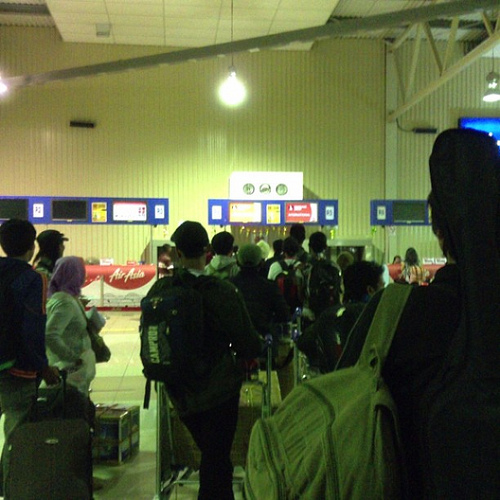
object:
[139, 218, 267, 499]
man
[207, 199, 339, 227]
panels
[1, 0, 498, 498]
airport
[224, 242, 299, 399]
person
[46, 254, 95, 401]
person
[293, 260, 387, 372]
person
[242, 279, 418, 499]
backpack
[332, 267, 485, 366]
shoulder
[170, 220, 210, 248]
black cap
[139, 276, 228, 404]
backpack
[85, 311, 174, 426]
floor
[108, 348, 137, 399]
tiles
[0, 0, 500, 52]
ceiling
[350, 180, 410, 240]
ground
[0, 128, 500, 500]
people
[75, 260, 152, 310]
counter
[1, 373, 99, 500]
suitcase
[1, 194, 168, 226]
electronic sign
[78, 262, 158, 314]
sign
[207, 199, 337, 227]
blue sign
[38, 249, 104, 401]
woman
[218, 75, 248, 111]
bright light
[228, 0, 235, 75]
wire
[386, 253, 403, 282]
person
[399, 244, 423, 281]
person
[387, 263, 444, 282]
counter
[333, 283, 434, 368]
person's shoulder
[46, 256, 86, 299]
headscarf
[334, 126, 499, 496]
person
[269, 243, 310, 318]
person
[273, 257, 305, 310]
backpack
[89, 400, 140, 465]
boxes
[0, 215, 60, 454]
man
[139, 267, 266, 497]
clothes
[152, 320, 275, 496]
luggage cart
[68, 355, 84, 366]
hand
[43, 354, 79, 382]
hip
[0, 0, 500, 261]
lines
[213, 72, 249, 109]
light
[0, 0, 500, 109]
supporting beam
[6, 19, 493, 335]
wall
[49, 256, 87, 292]
head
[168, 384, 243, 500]
legs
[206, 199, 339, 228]
tickets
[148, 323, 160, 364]
writing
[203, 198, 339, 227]
sign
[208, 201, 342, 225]
background